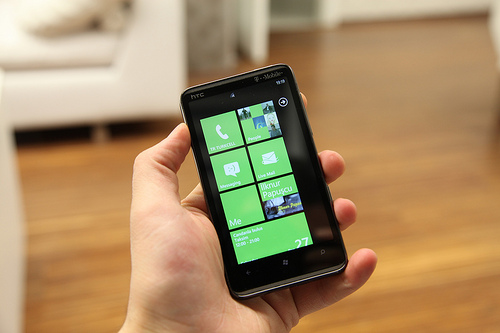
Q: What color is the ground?
A: Brown.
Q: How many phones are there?
A: One.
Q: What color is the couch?
A: White.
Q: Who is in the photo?
A: A person.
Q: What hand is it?
A: Left.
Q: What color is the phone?
A: Black.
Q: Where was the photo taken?
A: The living room.